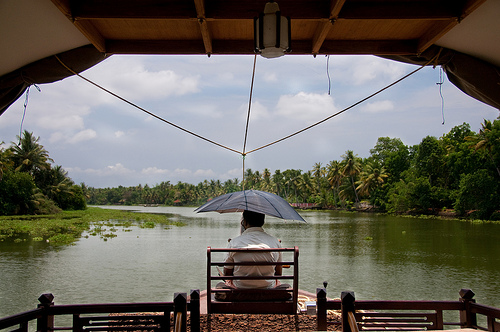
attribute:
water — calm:
[0, 206, 499, 330]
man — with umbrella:
[192, 187, 305, 298]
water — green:
[79, 207, 469, 288]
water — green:
[322, 231, 444, 292]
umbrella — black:
[210, 179, 315, 230]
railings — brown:
[42, 293, 197, 322]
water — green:
[56, 193, 177, 293]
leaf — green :
[25, 169, 30, 174]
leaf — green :
[14, 166, 24, 168]